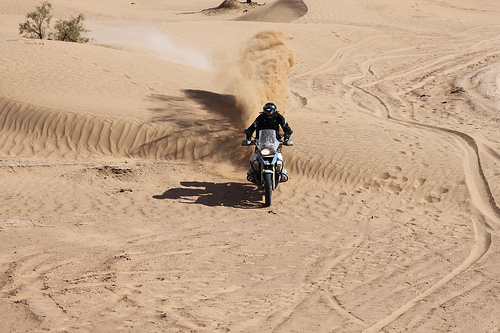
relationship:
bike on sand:
[240, 128, 290, 206] [289, 149, 383, 196]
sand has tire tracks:
[289, 149, 383, 196] [382, 76, 496, 210]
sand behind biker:
[289, 149, 383, 196] [239, 102, 296, 148]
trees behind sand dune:
[53, 11, 95, 43] [21, 39, 132, 159]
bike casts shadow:
[240, 128, 290, 206] [167, 170, 251, 220]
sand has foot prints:
[289, 149, 383, 196] [355, 148, 441, 227]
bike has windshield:
[225, 128, 302, 214] [254, 129, 285, 154]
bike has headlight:
[225, 128, 302, 214] [261, 148, 270, 156]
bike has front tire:
[225, 128, 302, 214] [262, 166, 277, 209]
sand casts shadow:
[231, 42, 264, 117] [194, 75, 240, 137]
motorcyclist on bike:
[239, 102, 296, 148] [240, 128, 290, 206]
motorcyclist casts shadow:
[239, 102, 296, 148] [167, 170, 251, 220]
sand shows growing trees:
[30, 44, 89, 75] [28, 4, 112, 54]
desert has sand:
[94, 15, 470, 139] [289, 149, 383, 196]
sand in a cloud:
[231, 42, 264, 117] [219, 32, 306, 99]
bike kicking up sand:
[240, 128, 290, 206] [231, 42, 264, 117]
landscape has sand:
[94, 15, 470, 139] [289, 149, 383, 196]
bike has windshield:
[240, 128, 290, 206] [254, 129, 285, 154]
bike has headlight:
[240, 128, 290, 206] [257, 142, 276, 161]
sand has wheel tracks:
[289, 149, 383, 196] [382, 76, 496, 210]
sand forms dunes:
[289, 149, 383, 196] [48, 55, 182, 173]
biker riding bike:
[245, 102, 293, 141] [240, 128, 290, 206]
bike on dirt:
[225, 128, 302, 214] [271, 21, 328, 110]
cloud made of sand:
[219, 32, 306, 99] [231, 42, 264, 117]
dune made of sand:
[21, 39, 132, 159] [289, 149, 383, 196]